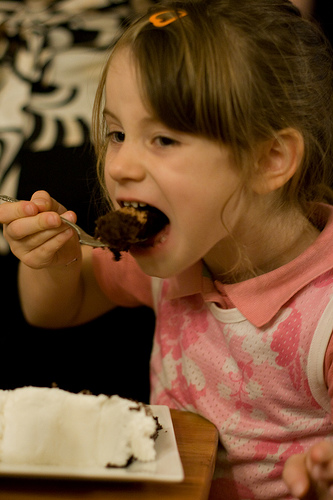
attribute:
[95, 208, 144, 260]
cake — chocolate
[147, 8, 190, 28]
clip — orange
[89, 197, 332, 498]
shirt — pink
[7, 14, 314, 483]
girl — little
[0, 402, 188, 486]
plate — white, square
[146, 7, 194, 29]
barrette — orange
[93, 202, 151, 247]
cake — chocolate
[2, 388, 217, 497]
table — wooden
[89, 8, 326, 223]
hair — brown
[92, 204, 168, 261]
cake — chocolate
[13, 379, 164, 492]
tray — square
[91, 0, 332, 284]
hair — light brown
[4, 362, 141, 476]
cake — chocolate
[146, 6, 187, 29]
clip — pink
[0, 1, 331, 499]
hair — brown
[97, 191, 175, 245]
mouth — open, wide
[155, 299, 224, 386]
print — pink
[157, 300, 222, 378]
print — floral, pink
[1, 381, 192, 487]
plate — white, square